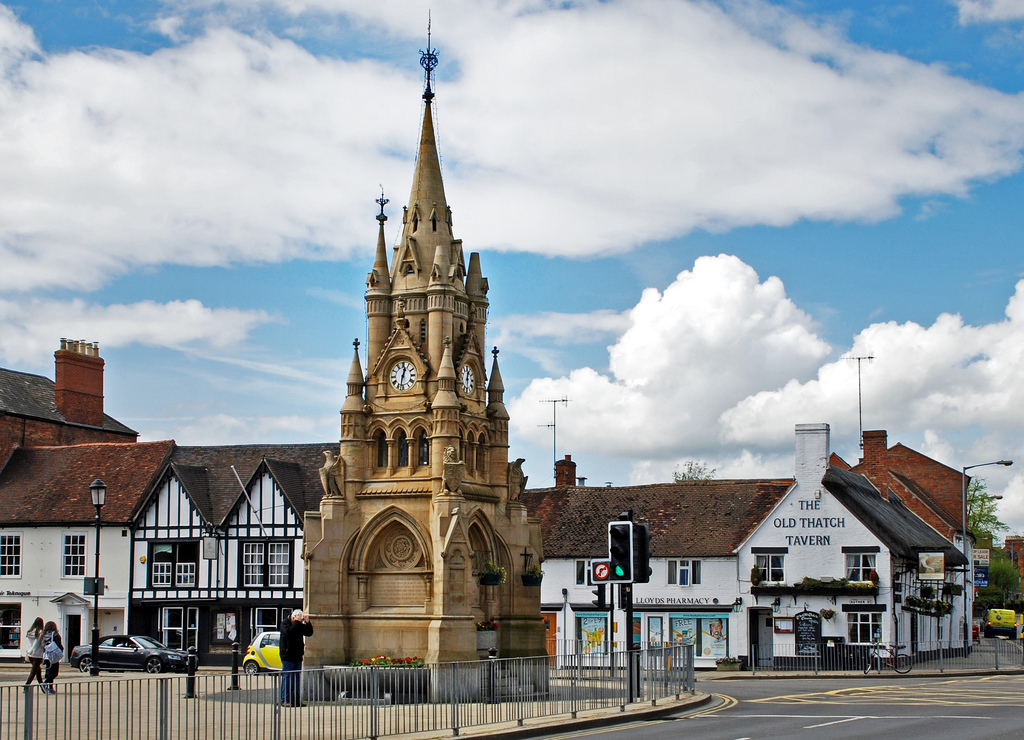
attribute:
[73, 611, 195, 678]
car — black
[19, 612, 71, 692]
people — enjoying the outdoors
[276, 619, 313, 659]
jacket — black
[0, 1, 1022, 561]
sky — light, blue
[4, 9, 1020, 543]
clouds — white